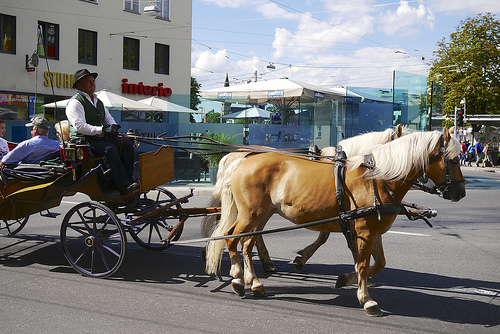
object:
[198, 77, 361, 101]
umrellas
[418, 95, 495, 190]
pedestrians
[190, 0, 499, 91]
sky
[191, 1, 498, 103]
clouds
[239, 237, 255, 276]
leg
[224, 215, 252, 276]
leg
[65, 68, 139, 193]
driver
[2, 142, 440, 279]
carriage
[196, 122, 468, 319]
tennis racket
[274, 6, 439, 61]
cloudy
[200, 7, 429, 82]
distant sky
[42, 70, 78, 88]
sign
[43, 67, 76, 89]
name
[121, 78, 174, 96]
name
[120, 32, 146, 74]
baby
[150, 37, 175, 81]
lettuce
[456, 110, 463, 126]
traffic signal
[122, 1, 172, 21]
windows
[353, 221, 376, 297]
leg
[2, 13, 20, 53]
window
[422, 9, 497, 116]
green tree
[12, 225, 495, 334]
street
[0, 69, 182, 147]
walls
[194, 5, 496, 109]
sky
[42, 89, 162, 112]
umbrella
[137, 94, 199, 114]
umbrella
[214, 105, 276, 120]
umbrella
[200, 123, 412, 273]
horse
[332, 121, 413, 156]
mane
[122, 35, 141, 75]
window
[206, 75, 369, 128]
tent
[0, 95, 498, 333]
parking lot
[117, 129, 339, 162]
reins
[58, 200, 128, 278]
spoke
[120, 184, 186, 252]
wheel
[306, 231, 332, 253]
leg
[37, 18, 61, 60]
window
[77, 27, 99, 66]
window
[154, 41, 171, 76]
window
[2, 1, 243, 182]
building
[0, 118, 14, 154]
passengers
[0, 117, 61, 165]
passengers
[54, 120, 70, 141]
passengers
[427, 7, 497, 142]
tree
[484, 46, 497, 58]
leaf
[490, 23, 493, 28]
leaf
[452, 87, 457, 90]
leaf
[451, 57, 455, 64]
leaf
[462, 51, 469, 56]
leaf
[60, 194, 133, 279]
wheel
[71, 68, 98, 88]
hat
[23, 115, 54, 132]
hat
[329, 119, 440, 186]
mane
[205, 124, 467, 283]
horse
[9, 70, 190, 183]
eatery